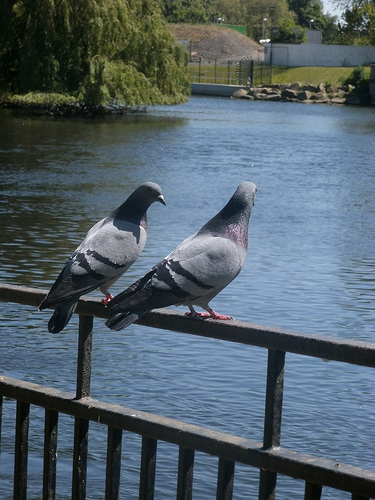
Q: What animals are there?
A: Birds.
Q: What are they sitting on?
A: The railing.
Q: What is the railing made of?
A: Iron.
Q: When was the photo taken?
A: Daytime.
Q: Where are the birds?
A: On the railing.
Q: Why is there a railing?
A: It is on a bridge.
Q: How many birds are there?
A: Two.